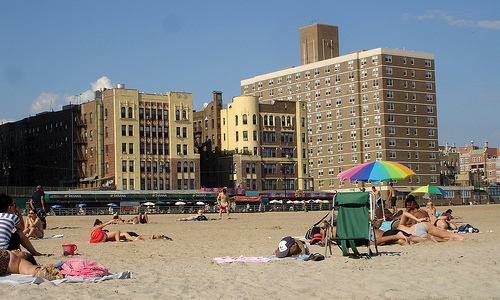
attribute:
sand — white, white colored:
[174, 271, 238, 299]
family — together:
[361, 161, 479, 255]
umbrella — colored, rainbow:
[336, 158, 422, 184]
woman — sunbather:
[1, 243, 46, 290]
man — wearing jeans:
[26, 185, 55, 219]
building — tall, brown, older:
[0, 88, 203, 194]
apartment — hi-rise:
[248, 22, 451, 189]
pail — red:
[58, 242, 80, 258]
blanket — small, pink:
[64, 258, 112, 280]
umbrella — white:
[143, 201, 155, 211]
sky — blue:
[128, 2, 278, 69]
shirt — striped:
[0, 212, 22, 249]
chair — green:
[332, 190, 375, 256]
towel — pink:
[209, 251, 270, 266]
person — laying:
[177, 208, 210, 222]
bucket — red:
[62, 241, 78, 255]